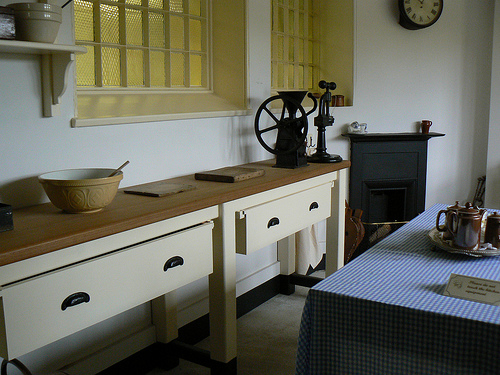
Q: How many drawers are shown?
A: Two.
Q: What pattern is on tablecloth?
A: Checked.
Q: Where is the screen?
A: Behind window.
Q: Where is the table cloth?
A: On table.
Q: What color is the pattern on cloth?
A: Blue and white.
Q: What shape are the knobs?
A: Half-moon.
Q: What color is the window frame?
A: Cream.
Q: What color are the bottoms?
A: Black.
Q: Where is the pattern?
A: On table cloth.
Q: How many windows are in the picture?
A: Two.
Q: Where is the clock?
A: On the wall.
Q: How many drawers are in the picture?
A: Two.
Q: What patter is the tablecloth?
A: Checkered.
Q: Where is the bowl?
A: On the counter.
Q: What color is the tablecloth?
A: Blue.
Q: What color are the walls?
A: White.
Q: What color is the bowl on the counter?
A: Yellow.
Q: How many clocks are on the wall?
A: One.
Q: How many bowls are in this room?
A: Three.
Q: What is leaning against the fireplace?
A: Bellows.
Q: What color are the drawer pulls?
A: Black.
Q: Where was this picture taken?
A: Museum.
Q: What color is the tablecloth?
A: Blue.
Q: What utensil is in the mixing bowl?
A: Wooden spoon.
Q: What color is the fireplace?
A: Black.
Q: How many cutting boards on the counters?
A: Two.